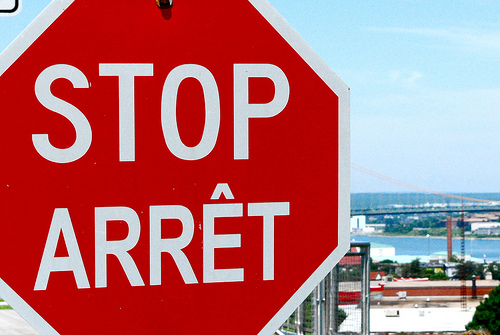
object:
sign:
[1, 0, 351, 335]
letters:
[30, 62, 291, 291]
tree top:
[464, 283, 499, 335]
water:
[349, 234, 500, 261]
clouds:
[361, 17, 497, 61]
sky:
[1, 0, 500, 193]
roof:
[337, 307, 477, 332]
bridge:
[350, 162, 499, 215]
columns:
[447, 216, 452, 262]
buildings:
[339, 202, 500, 280]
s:
[32, 63, 93, 163]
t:
[99, 63, 154, 162]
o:
[160, 64, 220, 161]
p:
[234, 63, 290, 159]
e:
[203, 203, 244, 283]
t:
[247, 202, 290, 280]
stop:
[32, 63, 289, 164]